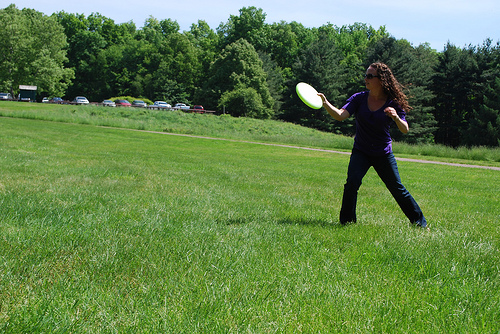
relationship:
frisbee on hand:
[292, 76, 326, 114] [317, 85, 329, 105]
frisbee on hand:
[295, 81, 324, 110] [315, 89, 331, 109]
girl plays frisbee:
[317, 56, 435, 232] [292, 76, 326, 114]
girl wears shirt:
[317, 56, 435, 232] [341, 91, 406, 138]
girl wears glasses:
[317, 61, 430, 230] [362, 74, 379, 79]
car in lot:
[74, 96, 89, 104] [53, 91, 211, 114]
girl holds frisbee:
[317, 61, 430, 230] [290, 76, 328, 110]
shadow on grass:
[212, 205, 339, 232] [175, 158, 338, 279]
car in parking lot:
[74, 96, 89, 104] [28, 85, 202, 112]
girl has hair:
[317, 61, 430, 230] [368, 58, 411, 110]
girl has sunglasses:
[317, 61, 430, 230] [359, 68, 380, 84]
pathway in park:
[102, 117, 300, 149] [6, 103, 496, 332]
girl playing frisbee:
[317, 61, 430, 230] [294, 79, 323, 110]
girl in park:
[317, 61, 430, 230] [6, 103, 496, 332]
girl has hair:
[317, 61, 430, 230] [371, 63, 412, 115]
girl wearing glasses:
[317, 61, 430, 230] [362, 74, 375, 82]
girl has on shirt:
[317, 61, 430, 230] [343, 90, 407, 148]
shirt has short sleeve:
[344, 90, 408, 154] [342, 97, 355, 115]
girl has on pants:
[317, 61, 430, 230] [338, 149, 424, 222]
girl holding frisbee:
[317, 61, 430, 230] [290, 76, 328, 110]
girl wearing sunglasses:
[317, 61, 430, 230] [357, 70, 380, 82]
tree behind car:
[3, 5, 274, 99] [1, 91, 13, 104]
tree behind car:
[3, 5, 274, 99] [38, 96, 55, 105]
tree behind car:
[3, 5, 274, 99] [70, 92, 92, 104]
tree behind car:
[3, 5, 274, 99] [101, 93, 118, 108]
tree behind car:
[3, 5, 274, 99] [116, 96, 133, 109]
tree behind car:
[3, 5, 274, 99] [130, 99, 148, 106]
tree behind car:
[3, 5, 274, 99] [149, 96, 172, 110]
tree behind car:
[3, 5, 274, 99] [171, 100, 192, 111]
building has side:
[12, 80, 42, 103] [32, 85, 37, 99]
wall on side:
[32, 87, 37, 102] [32, 85, 37, 99]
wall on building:
[32, 87, 37, 102] [12, 80, 42, 103]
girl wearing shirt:
[317, 61, 430, 230] [343, 87, 405, 150]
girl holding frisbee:
[317, 61, 430, 230] [294, 80, 324, 108]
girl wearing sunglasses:
[317, 61, 430, 230] [360, 70, 380, 80]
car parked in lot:
[73, 94, 92, 107] [2, 90, 225, 115]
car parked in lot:
[74, 96, 89, 104] [4, 87, 226, 115]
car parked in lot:
[113, 97, 132, 109] [4, 87, 226, 115]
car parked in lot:
[152, 97, 175, 111] [2, 91, 215, 113]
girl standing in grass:
[317, 61, 430, 230] [5, 116, 326, 330]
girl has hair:
[317, 56, 435, 232] [370, 57, 416, 110]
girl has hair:
[317, 56, 435, 232] [366, 58, 418, 115]